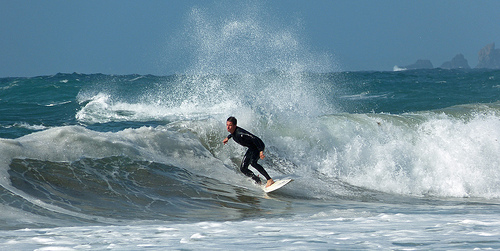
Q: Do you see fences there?
A: No, there are no fences.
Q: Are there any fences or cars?
A: No, there are no fences or cars.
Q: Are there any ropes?
A: No, there are no ropes.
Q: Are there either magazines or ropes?
A: No, there are no ropes or magazines.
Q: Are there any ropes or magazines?
A: No, there are no ropes or magazines.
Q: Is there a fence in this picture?
A: No, there are no fences.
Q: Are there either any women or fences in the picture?
A: No, there are no fences or women.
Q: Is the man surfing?
A: Yes, the man is surfing.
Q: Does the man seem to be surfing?
A: Yes, the man is surfing.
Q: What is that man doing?
A: The man is surfing.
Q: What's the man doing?
A: The man is surfing.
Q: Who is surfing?
A: The man is surfing.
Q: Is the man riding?
A: No, the man is surfing.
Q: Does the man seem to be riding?
A: No, the man is surfing.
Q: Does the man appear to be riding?
A: No, the man is surfing.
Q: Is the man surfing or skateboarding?
A: The man is surfing.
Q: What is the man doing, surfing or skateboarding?
A: The man is surfing.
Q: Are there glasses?
A: No, there are no glasses.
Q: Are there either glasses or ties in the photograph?
A: No, there are no glasses or ties.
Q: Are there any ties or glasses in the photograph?
A: No, there are no glasses or ties.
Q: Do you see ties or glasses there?
A: No, there are no glasses or ties.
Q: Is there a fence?
A: No, there are no fences.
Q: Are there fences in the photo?
A: No, there are no fences.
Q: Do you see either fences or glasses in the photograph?
A: No, there are no fences or glasses.